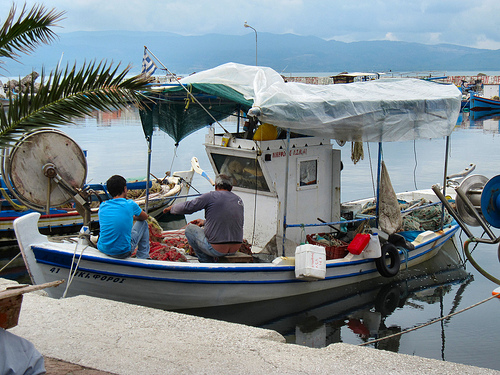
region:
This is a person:
[165, 165, 257, 272]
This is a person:
[89, 165, 169, 272]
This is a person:
[159, 174, 254, 270]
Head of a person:
[80, 171, 153, 211]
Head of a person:
[210, 160, 239, 200]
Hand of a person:
[152, 185, 212, 218]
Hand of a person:
[129, 199, 156, 221]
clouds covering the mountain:
[256, 10, 342, 43]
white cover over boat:
[279, 78, 449, 145]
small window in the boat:
[285, 153, 325, 188]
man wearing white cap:
[200, 163, 247, 191]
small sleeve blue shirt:
[92, 196, 152, 257]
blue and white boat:
[466, 87, 490, 124]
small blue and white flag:
[126, 53, 172, 82]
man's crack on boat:
[211, 238, 241, 258]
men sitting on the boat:
[91, 158, 257, 258]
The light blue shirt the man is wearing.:
[97, 199, 138, 252]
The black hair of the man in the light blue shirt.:
[106, 172, 125, 194]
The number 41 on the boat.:
[43, 264, 62, 274]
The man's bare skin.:
[215, 246, 240, 251]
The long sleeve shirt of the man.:
[171, 190, 246, 244]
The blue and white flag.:
[138, 51, 153, 76]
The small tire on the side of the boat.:
[372, 242, 402, 277]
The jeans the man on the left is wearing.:
[132, 217, 149, 260]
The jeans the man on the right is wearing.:
[182, 222, 234, 264]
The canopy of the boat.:
[141, 65, 463, 142]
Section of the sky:
[278, 3, 439, 37]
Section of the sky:
[373, 0, 498, 47]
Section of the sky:
[61, 0, 238, 32]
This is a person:
[161, 175, 253, 276]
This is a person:
[86, 169, 168, 264]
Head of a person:
[201, 170, 245, 200]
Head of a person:
[98, 168, 138, 203]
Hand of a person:
[156, 190, 215, 220]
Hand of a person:
[126, 199, 153, 225]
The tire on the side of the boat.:
[374, 242, 399, 277]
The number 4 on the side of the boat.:
[49, 264, 57, 276]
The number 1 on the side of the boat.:
[53, 264, 61, 274]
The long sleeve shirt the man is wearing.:
[167, 192, 244, 248]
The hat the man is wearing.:
[207, 174, 233, 188]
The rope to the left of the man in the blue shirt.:
[57, 232, 84, 299]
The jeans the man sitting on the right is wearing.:
[181, 222, 213, 258]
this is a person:
[79, 165, 161, 260]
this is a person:
[165, 163, 250, 260]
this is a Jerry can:
[283, 236, 333, 290]